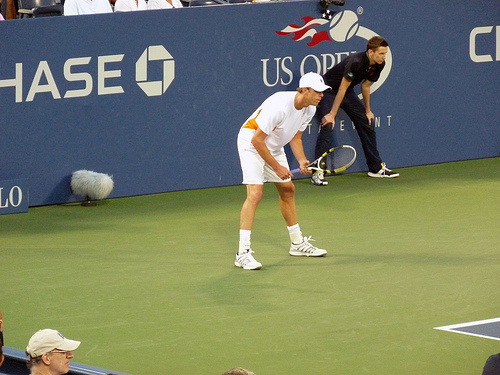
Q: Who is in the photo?
A: Players.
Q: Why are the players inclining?
A: They are playing.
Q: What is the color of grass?
A: Green.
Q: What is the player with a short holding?
A: Tennis rack.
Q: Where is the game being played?
A: Tennis court.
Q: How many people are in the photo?
A: 3.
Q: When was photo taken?
A: Day time.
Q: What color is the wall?
A: Blue with white writings.